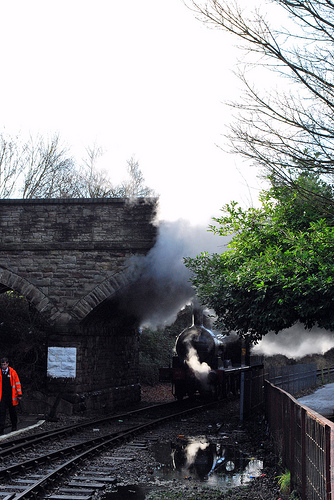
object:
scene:
[0, 54, 334, 474]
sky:
[96, 21, 165, 137]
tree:
[213, 31, 332, 229]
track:
[30, 417, 187, 452]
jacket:
[0, 365, 23, 406]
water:
[297, 381, 334, 419]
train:
[156, 309, 236, 411]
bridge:
[0, 196, 161, 418]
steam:
[250, 316, 334, 362]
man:
[0, 351, 23, 434]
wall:
[42, 231, 105, 269]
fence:
[222, 367, 334, 499]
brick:
[50, 274, 77, 324]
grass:
[272, 470, 292, 489]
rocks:
[263, 452, 272, 494]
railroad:
[54, 395, 216, 470]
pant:
[0, 398, 18, 436]